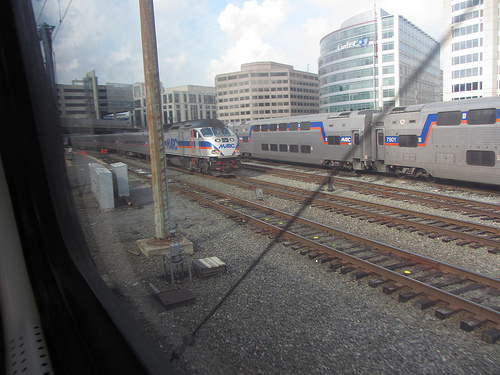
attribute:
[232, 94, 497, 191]
train — gray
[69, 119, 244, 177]
train — red , blue , silver 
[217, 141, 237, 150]
writing — blue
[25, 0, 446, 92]
sky — blue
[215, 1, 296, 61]
clouds — White 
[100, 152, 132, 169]
train track — empty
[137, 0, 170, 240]
pole — gray, metal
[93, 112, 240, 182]
train — silver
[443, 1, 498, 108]
building — white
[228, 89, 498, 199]
train — silver , blue, orange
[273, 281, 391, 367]
gravel — grey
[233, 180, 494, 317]
tracks — empty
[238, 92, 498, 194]
engine — train engine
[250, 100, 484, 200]
train cars — double decker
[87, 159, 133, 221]
boxes — on the ground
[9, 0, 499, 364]
window — clear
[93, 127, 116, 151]
train car — silver , blue , red 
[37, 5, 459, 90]
clouds — white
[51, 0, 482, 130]
building — white